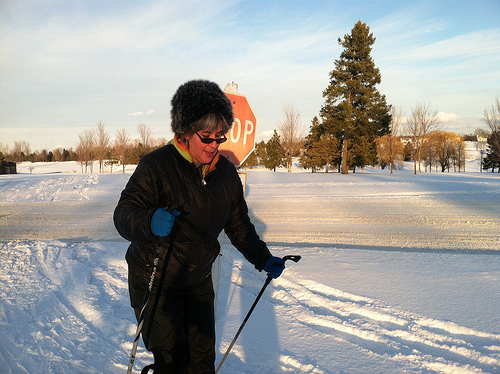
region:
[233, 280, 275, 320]
part of a hooker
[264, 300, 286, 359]
edge of a shade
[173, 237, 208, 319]
part of a jacket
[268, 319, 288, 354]
edge of a shade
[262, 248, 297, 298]
part of a glove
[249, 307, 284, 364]
part of a shade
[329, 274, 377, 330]
part of a track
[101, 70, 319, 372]
Woman is in the foreground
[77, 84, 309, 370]
Woman is skiing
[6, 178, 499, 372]
Snow is covering the ground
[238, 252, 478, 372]
Tracks are in the snow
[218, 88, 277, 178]
A stop sign in the background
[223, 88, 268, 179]
Stop sign is discolored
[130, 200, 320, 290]
Woman is wearing blue gloves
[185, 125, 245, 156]
Woman is wearing sunglasses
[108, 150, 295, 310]
Woman is wearing a black coat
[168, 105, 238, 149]
Woman has gray colored hair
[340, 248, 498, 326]
The ground is snow covered.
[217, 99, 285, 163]
the sign is red.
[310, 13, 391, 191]
The tree is tall.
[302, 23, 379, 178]
The tree is green.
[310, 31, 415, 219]
The tree is leafy.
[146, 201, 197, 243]
She is wearing blue gloves.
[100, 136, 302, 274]
She has a black jacket.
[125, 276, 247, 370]
She has black pants.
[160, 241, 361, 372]
The woman is holding poles.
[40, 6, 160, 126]
The sky is cloudy.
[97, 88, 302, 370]
a woman riding skis in the snow.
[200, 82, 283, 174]
a red stop sign.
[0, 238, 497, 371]
a bunch of tracks in the snow.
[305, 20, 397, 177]
a very tall pine tree.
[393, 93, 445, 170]
a leafless tree.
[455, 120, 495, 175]
a patch of snow.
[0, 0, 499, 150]
a cloudy blue sky.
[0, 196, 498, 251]
a snow covered road.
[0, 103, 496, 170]
a forest filled with trees.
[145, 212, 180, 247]
a right blue glove.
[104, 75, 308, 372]
Woman dressed in skiing gear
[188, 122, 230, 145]
Sunglasses on woman's face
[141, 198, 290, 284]
Blue winter gloves on woman's hands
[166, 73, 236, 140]
Furry black hat on woman's head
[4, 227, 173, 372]
Snowy trails behind skiing woman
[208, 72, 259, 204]
Red stop sign behind woman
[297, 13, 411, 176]
Tall evergreen tree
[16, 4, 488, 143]
Blue sky covered in whispy white clouds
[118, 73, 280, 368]
Elderly woman dressed in black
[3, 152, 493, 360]
Snow covering the road and street